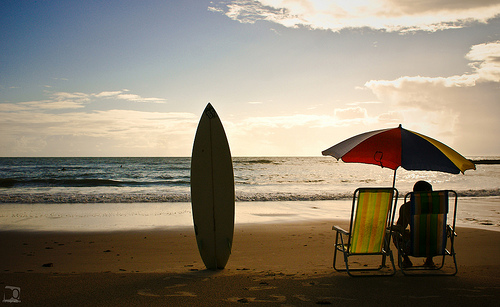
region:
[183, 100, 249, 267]
surfboard on tan sandy beach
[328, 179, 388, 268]
yellow and green beach chair on tan sandy beach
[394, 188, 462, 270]
yellow and green beach chair on tan sandy beach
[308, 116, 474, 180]
multi colored open umbrella yellow on tan sandy beach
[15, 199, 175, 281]
brown wet sand on beach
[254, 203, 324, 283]
brown wet sand on beach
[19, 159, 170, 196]
waves in blue and white ocean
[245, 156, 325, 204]
waves in blue and white ocean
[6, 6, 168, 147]
white clouds against blue sky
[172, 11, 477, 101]
white clouds against blue sky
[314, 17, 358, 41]
edge of a cloud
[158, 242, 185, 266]
part of a beach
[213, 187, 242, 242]
edge of a board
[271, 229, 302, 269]
part of some sand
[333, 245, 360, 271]
part of a metal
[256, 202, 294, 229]
edge of a shore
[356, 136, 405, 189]
edge of an umbrella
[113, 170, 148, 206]
part of a wave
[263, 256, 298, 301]
part of a beach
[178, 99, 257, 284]
a surfboard on a beach.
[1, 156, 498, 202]
an ocean filled with water.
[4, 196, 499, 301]
a sandy waved covered beach.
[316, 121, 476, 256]
a red umbrella over a person.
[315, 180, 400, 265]
a chair sitting on a beach.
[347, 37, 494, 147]
a large gray cloudy sky.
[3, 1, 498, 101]
a section of a blue sky.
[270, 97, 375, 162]
a setting sun.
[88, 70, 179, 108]
a cloud in a blue sky.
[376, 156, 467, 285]
a hipster.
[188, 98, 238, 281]
surfboard stuck in and standing in the sand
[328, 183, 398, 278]
empty multicolored chair on a beach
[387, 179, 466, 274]
man sitting on a chair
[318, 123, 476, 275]
two chairs and a man under a colorful umbrella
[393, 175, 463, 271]
man sitting on a chair at the beach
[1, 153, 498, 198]
blue waters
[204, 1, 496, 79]
white clouds in a blue sky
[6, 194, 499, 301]
beach grounds made of sand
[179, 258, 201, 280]
print in the sand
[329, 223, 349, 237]
chair arm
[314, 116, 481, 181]
big red, white, yellow, and blue umbrella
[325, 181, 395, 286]
yellow, green, and orange striped beach chair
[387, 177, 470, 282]
person sitting in a beach chair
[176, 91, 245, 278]
vertical standing surf board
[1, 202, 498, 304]
brown sandy beach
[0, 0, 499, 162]
mostly blue slightly cloudy sky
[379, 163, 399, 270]
pole to umbrella stuck in the sand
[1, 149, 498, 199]
beautiful blue ocean surf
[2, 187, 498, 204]
foamy ocean waves lapping the shore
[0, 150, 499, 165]
horizon line